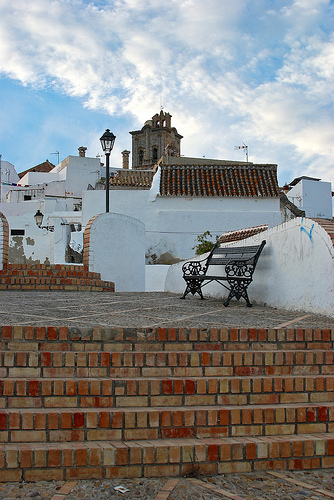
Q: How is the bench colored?
A: Black.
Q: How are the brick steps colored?
A: Brown, tan, light brown, and red.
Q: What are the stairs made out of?
A: Bricks.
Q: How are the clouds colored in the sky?
A: White.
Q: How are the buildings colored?
A: White.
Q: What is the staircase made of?
A: Bricks.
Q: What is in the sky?
A: Clouds.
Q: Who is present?
A: Nobody.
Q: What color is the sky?
A: Blue.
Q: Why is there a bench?
A: Resting.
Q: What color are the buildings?
A: White.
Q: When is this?
A: Daytime.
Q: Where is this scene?
A: On a sidewalk.